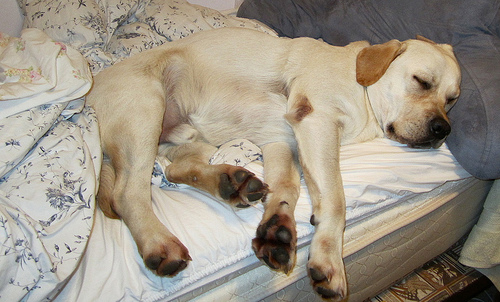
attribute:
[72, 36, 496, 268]
dog — white, sleeping, lying, brown, tan, asleep, sleepig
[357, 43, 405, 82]
ear — brown, white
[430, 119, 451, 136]
nose — black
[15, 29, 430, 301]
mattress — white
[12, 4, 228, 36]
comforter — white, gray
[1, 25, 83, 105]
blanket — white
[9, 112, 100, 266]
sheet — white, green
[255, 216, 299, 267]
paw — black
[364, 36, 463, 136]
head — white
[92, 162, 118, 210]
tail — white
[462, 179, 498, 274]
towel — blue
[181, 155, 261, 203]
leg — black